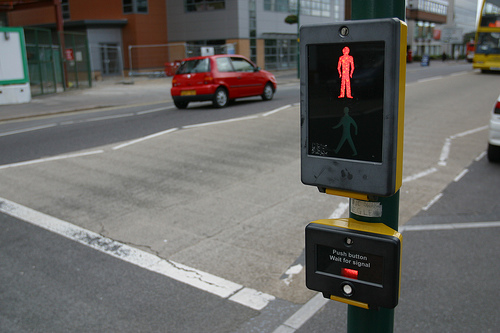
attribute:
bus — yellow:
[467, 2, 499, 68]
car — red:
[175, 52, 277, 102]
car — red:
[132, 37, 296, 163]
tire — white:
[486, 145, 499, 167]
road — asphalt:
[11, 112, 307, 329]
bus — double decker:
[465, 4, 498, 81]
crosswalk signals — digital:
[300, 14, 399, 192]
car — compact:
[160, 42, 282, 117]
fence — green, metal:
[21, 27, 96, 101]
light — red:
[338, 261, 362, 281]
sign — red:
[62, 49, 74, 61]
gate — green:
[32, 39, 107, 97]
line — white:
[0, 196, 275, 311]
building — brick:
[41, 11, 499, 113]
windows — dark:
[221, 42, 254, 89]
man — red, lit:
[309, 52, 366, 114]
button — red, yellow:
[313, 234, 379, 296]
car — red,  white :
[170, 53, 277, 108]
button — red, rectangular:
[337, 265, 364, 277]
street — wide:
[102, 133, 284, 263]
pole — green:
[341, 1, 411, 331]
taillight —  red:
[494, 100, 499, 114]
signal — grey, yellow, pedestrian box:
[291, 19, 421, 173]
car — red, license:
[151, 54, 309, 111]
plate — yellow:
[168, 77, 235, 115]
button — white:
[342, 282, 350, 294]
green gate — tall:
[32, 14, 96, 98]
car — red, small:
[151, 45, 294, 113]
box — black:
[301, 212, 405, 313]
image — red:
[335, 44, 358, 100]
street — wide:
[0, 53, 495, 329]